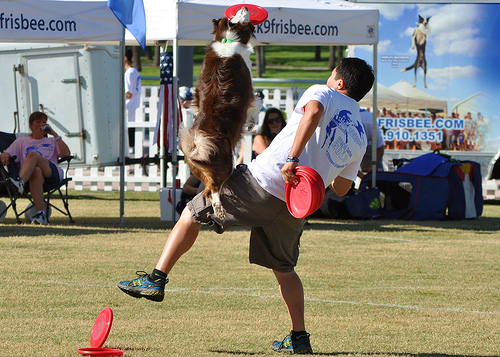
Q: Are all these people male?
A: No, they are both male and female.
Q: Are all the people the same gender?
A: No, they are both male and female.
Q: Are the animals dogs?
A: Yes, all the animals are dogs.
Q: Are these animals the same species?
A: Yes, all the animals are dogs.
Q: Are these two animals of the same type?
A: Yes, all the animals are dogs.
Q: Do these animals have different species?
A: No, all the animals are dogs.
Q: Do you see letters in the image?
A: Yes, there are letters.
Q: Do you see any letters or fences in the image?
A: Yes, there are letters.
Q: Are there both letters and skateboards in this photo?
A: No, there are letters but no skateboards.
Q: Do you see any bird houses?
A: No, there are no bird houses.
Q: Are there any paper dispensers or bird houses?
A: No, there are no bird houses or paper dispensers.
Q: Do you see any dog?
A: Yes, there is a dog.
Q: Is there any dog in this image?
A: Yes, there is a dog.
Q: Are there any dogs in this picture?
A: Yes, there is a dog.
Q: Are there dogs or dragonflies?
A: Yes, there is a dog.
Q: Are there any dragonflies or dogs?
A: Yes, there is a dog.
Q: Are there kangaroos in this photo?
A: No, there are no kangaroos.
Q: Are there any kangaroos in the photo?
A: No, there are no kangaroos.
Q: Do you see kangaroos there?
A: No, there are no kangaroos.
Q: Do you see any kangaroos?
A: No, there are no kangaroos.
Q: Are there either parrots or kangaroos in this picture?
A: No, there are no kangaroos or parrots.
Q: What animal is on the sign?
A: The dog is on the sign.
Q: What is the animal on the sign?
A: The animal is a dog.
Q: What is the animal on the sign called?
A: The animal is a dog.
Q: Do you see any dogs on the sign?
A: Yes, there is a dog on the sign.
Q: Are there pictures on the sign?
A: No, there is a dog on the sign.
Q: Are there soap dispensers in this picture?
A: No, there are no soap dispensers.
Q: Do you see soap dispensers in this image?
A: No, there are no soap dispensers.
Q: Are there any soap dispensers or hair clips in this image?
A: No, there are no soap dispensers or hair clips.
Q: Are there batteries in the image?
A: No, there are no batteries.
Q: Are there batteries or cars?
A: No, there are no batteries or cars.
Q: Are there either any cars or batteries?
A: No, there are no batteries or cars.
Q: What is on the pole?
A: The American flag is on the pole.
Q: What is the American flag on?
A: The American flag is on the pole.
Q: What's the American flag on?
A: The American flag is on the pole.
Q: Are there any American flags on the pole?
A: Yes, there is an American flag on the pole.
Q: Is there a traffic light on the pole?
A: No, there is an American flag on the pole.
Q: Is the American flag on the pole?
A: Yes, the American flag is on the pole.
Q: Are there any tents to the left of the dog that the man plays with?
A: No, there is an American flag to the left of the dog.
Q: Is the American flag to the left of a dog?
A: Yes, the American flag is to the left of a dog.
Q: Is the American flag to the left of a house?
A: No, the American flag is to the left of a dog.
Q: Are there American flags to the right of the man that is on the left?
A: Yes, there is an American flag to the right of the man.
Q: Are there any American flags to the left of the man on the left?
A: No, the American flag is to the right of the man.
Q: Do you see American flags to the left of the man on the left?
A: No, the American flag is to the right of the man.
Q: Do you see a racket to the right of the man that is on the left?
A: No, there is an American flag to the right of the man.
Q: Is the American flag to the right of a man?
A: Yes, the American flag is to the right of a man.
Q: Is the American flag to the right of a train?
A: No, the American flag is to the right of a man.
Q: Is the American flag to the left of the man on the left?
A: No, the American flag is to the right of the man.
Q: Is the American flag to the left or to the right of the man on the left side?
A: The American flag is to the right of the man.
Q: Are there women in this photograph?
A: Yes, there is a woman.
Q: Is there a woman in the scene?
A: Yes, there is a woman.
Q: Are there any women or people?
A: Yes, there is a woman.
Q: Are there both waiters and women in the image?
A: No, there is a woman but no waiters.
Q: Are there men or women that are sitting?
A: Yes, the woman is sitting.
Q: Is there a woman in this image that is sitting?
A: Yes, there is a woman that is sitting.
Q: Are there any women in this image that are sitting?
A: Yes, there is a woman that is sitting.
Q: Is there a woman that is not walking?
A: Yes, there is a woman that is sitting.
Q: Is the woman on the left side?
A: Yes, the woman is on the left of the image.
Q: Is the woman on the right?
A: No, the woman is on the left of the image.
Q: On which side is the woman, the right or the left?
A: The woman is on the left of the image.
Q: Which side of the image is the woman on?
A: The woman is on the left of the image.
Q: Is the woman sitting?
A: Yes, the woman is sitting.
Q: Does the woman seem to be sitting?
A: Yes, the woman is sitting.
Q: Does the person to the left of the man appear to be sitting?
A: Yes, the woman is sitting.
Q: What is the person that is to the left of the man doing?
A: The woman is sitting.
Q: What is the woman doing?
A: The woman is sitting.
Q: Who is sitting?
A: The woman is sitting.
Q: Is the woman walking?
A: No, the woman is sitting.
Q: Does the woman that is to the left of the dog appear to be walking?
A: No, the woman is sitting.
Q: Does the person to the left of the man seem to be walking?
A: No, the woman is sitting.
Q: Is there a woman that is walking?
A: No, there is a woman but she is sitting.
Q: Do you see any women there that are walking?
A: No, there is a woman but she is sitting.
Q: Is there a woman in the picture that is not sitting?
A: No, there is a woman but she is sitting.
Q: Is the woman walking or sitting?
A: The woman is sitting.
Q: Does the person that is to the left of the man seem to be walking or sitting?
A: The woman is sitting.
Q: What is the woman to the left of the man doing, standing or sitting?
A: The woman is sitting.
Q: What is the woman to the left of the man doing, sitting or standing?
A: The woman is sitting.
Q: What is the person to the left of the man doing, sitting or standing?
A: The woman is sitting.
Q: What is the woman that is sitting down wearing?
A: The woman is wearing a shirt.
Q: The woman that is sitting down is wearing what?
A: The woman is wearing a shirt.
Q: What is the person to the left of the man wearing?
A: The woman is wearing a shirt.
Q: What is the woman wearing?
A: The woman is wearing a shirt.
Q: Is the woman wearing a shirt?
A: Yes, the woman is wearing a shirt.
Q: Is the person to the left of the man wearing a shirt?
A: Yes, the woman is wearing a shirt.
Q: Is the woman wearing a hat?
A: No, the woman is wearing a shirt.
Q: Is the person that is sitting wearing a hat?
A: No, the woman is wearing a shirt.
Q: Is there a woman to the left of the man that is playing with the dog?
A: Yes, there is a woman to the left of the man.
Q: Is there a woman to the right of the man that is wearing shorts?
A: No, the woman is to the left of the man.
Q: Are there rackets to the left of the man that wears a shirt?
A: No, there is a woman to the left of the man.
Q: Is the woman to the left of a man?
A: Yes, the woman is to the left of a man.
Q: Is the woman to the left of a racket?
A: No, the woman is to the left of a man.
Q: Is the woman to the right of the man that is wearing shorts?
A: No, the woman is to the left of the man.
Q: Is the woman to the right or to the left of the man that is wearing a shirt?
A: The woman is to the left of the man.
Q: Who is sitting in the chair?
A: The woman is sitting in the chair.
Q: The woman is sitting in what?
A: The woman is sitting in the chair.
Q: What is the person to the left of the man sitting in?
A: The woman is sitting in the chair.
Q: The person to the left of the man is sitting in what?
A: The woman is sitting in the chair.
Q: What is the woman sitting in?
A: The woman is sitting in the chair.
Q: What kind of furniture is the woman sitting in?
A: The woman is sitting in the chair.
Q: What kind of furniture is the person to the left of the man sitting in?
A: The woman is sitting in the chair.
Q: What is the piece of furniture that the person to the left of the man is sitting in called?
A: The piece of furniture is a chair.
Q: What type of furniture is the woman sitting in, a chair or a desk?
A: The woman is sitting in a chair.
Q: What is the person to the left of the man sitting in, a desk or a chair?
A: The woman is sitting in a chair.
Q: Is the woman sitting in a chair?
A: Yes, the woman is sitting in a chair.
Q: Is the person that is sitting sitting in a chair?
A: Yes, the woman is sitting in a chair.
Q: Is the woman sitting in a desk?
A: No, the woman is sitting in a chair.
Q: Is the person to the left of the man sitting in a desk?
A: No, the woman is sitting in a chair.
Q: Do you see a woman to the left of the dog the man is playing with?
A: Yes, there is a woman to the left of the dog.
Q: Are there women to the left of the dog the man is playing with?
A: Yes, there is a woman to the left of the dog.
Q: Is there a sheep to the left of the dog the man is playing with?
A: No, there is a woman to the left of the dog.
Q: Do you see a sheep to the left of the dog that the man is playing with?
A: No, there is a woman to the left of the dog.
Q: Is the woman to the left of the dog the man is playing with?
A: Yes, the woman is to the left of the dog.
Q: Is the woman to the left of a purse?
A: No, the woman is to the left of the dog.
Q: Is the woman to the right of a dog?
A: No, the woman is to the left of a dog.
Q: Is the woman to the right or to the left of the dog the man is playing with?
A: The woman is to the left of the dog.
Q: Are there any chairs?
A: Yes, there is a chair.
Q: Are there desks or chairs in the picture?
A: Yes, there is a chair.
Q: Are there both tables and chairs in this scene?
A: No, there is a chair but no tables.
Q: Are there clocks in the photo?
A: No, there are no clocks.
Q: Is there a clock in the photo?
A: No, there are no clocks.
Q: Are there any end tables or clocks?
A: No, there are no clocks or end tables.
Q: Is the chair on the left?
A: Yes, the chair is on the left of the image.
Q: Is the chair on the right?
A: No, the chair is on the left of the image.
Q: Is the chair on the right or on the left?
A: The chair is on the left of the image.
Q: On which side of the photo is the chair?
A: The chair is on the left of the image.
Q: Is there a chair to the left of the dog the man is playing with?
A: Yes, there is a chair to the left of the dog.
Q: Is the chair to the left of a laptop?
A: No, the chair is to the left of the dog.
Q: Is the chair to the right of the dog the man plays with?
A: No, the chair is to the left of the dog.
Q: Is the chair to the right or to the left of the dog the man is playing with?
A: The chair is to the left of the dog.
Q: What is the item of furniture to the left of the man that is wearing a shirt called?
A: The piece of furniture is a chair.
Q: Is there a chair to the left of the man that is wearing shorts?
A: Yes, there is a chair to the left of the man.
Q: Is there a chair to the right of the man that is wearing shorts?
A: No, the chair is to the left of the man.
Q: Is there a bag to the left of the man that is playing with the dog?
A: No, there is a chair to the left of the man.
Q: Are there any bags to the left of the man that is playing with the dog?
A: No, there is a chair to the left of the man.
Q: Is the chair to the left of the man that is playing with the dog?
A: Yes, the chair is to the left of the man.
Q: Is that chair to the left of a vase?
A: No, the chair is to the left of the man.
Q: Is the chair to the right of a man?
A: No, the chair is to the left of a man.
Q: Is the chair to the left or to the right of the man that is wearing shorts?
A: The chair is to the left of the man.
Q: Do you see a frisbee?
A: Yes, there is a frisbee.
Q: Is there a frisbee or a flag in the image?
A: Yes, there is a frisbee.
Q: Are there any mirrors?
A: No, there are no mirrors.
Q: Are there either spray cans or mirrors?
A: No, there are no mirrors or spray cans.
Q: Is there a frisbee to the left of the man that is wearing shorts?
A: Yes, there is a frisbee to the left of the man.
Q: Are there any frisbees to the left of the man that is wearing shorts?
A: Yes, there is a frisbee to the left of the man.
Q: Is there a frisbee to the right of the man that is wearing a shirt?
A: No, the frisbee is to the left of the man.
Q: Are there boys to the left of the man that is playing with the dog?
A: No, there is a frisbee to the left of the man.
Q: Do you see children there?
A: No, there are no children.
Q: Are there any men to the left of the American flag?
A: Yes, there is a man to the left of the American flag.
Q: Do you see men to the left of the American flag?
A: Yes, there is a man to the left of the American flag.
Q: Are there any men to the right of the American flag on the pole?
A: No, the man is to the left of the American flag.